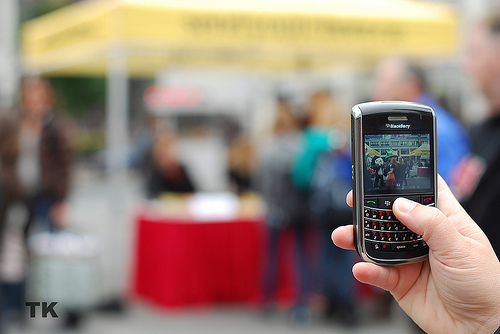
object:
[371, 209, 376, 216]
number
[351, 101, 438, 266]
phone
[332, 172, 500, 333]
man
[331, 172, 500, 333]
hand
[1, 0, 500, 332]
picture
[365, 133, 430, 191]
screen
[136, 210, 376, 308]
table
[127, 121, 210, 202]
people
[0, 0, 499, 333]
background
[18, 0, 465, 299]
tent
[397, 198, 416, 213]
fingernail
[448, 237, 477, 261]
wrinkles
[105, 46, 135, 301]
pole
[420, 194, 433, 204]
buttons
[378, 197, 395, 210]
button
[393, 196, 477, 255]
thumb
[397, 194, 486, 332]
palm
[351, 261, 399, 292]
pinky finger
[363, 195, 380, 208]
button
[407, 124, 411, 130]
letters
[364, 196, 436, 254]
keyboard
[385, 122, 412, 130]
logo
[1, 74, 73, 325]
bystander